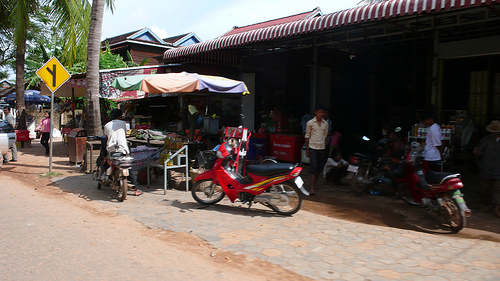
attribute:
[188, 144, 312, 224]
motorcycle — red, black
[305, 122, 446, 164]
shirts — light-colored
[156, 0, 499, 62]
fabric — red, white, long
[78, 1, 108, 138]
palm tree — curved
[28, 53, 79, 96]
traffic sign — yellow, black, rombus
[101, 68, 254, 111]
panel — orange, blue, green, multicolored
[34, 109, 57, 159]
"person — wearing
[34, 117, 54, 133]
shirt — pink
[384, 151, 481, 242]
scooter — red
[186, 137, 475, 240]
scooters — red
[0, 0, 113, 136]
trees — palm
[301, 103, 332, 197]
man — walking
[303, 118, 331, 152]
shirt — yellow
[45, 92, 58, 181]
pole — metal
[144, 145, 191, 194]
chair — blue